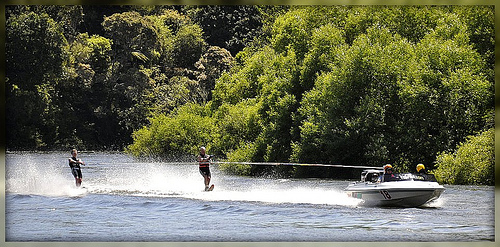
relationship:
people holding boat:
[194, 146, 219, 193] [340, 168, 448, 209]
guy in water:
[65, 149, 90, 188] [4, 148, 494, 236]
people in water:
[194, 146, 219, 193] [4, 148, 494, 236]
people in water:
[380, 163, 398, 182] [4, 148, 494, 236]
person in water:
[412, 158, 433, 179] [4, 148, 494, 236]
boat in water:
[340, 168, 448, 209] [4, 148, 494, 236]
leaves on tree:
[254, 47, 320, 115] [124, 2, 493, 183]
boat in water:
[340, 168, 448, 209] [228, 167, 357, 239]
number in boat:
[386, 190, 396, 202] [340, 163, 452, 211]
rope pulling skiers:
[85, 158, 385, 180] [188, 141, 218, 196]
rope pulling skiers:
[85, 158, 385, 180] [61, 140, 88, 186]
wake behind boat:
[230, 175, 338, 197] [346, 165, 441, 202]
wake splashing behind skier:
[5, 152, 493, 242] [192, 142, 218, 194]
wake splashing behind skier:
[5, 152, 493, 242] [64, 146, 91, 193]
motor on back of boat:
[358, 166, 371, 182] [340, 168, 448, 209]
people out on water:
[68, 144, 210, 189] [5, 191, 366, 242]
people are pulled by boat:
[194, 146, 219, 193] [323, 152, 455, 216]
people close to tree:
[380, 160, 399, 184] [427, 127, 497, 186]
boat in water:
[348, 157, 443, 212] [4, 148, 494, 236]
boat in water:
[340, 168, 448, 209] [39, 204, 365, 236]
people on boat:
[380, 163, 398, 182] [342, 165, 446, 207]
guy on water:
[65, 142, 90, 188] [4, 161, 497, 236]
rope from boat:
[87, 161, 384, 171] [344, 161, 446, 206]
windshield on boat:
[383, 167, 433, 184] [304, 114, 470, 230]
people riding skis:
[194, 146, 219, 193] [178, 127, 262, 210]